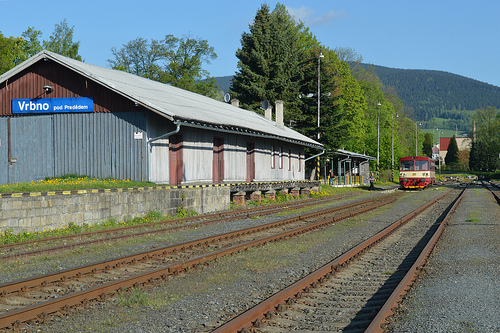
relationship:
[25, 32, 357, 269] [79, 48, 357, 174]
building with roof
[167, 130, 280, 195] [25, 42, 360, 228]
doors of building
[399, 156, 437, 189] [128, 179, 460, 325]
train of tracks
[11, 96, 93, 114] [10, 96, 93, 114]
sign printed on sign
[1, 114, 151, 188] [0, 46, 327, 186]
aluminum siding covering barn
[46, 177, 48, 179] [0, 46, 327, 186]
flower growing next to barn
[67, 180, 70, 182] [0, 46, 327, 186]
flower growing next to barn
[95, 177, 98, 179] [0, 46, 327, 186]
flower growing next to barn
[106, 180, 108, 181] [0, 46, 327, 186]
flower growing next to barn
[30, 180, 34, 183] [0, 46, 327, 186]
flower growing next to barn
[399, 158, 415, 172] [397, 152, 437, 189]
window built into train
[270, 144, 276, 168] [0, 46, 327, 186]
window built into barn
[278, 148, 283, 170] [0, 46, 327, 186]
window built into barn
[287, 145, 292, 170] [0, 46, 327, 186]
window built into barn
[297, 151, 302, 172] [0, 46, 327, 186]
window built into barn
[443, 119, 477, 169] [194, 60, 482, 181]
building standing in background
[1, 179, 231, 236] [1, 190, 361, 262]
wall built next to track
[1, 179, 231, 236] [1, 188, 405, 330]
wall built next to track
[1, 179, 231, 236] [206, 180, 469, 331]
wall built next to track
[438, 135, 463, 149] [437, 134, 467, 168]
roof covering building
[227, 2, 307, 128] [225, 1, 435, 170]
tree standing in row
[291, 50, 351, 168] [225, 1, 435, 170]
tree standing in row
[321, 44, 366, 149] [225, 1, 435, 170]
tree standing in row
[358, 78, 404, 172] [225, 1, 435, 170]
tree standing in row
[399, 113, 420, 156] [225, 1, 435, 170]
tree standing in row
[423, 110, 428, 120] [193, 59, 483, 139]
tree growing on hillside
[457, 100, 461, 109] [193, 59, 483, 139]
tree growing on hillside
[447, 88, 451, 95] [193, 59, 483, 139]
tree growing on hillside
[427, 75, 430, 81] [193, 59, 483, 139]
tree growing on hillside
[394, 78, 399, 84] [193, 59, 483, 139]
tree growing on hillside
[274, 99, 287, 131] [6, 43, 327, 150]
chimney mounted on roof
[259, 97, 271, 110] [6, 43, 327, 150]
satellite dish mounted on roof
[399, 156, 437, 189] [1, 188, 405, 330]
train riding on track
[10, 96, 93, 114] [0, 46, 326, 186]
sign hanging on building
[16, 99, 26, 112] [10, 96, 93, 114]
letter v printed on sign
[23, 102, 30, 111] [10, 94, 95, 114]
letter r printed on sign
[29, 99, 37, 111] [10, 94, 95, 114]
letter b printed on sign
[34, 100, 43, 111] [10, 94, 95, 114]
letter n printed on sign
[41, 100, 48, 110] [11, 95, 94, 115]
letter o printed on sign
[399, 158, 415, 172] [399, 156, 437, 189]
window built into train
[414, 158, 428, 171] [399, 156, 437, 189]
right window built into train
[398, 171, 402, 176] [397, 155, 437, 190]
headlight mounted on trolley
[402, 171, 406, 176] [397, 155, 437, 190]
headlight mounted on trolley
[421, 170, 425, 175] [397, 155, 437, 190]
headlight mounted on trolley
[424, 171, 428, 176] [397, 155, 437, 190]
headlight mounted on trolley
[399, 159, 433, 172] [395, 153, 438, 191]
front windshield on a train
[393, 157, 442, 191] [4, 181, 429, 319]
train on a track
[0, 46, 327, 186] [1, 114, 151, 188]
barn with aluminum siding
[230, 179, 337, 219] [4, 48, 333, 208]
porch near barn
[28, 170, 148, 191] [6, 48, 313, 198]
flowers near barn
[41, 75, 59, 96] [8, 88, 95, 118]
light above sign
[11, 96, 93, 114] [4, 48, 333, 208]
sign on a barn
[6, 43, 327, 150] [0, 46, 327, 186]
roof on a barn